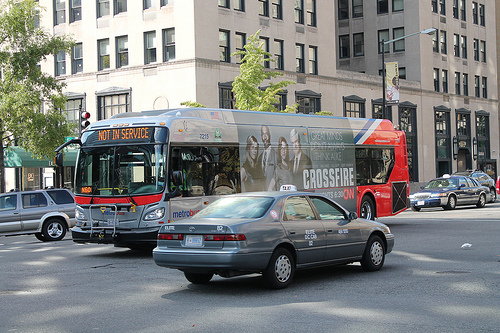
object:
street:
[0, 194, 500, 333]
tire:
[34, 218, 67, 243]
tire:
[261, 246, 297, 291]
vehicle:
[0, 188, 78, 244]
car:
[149, 184, 395, 291]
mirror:
[349, 212, 358, 221]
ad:
[230, 111, 360, 220]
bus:
[53, 106, 411, 250]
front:
[70, 116, 171, 244]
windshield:
[74, 126, 171, 198]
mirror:
[54, 153, 63, 167]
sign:
[80, 126, 155, 146]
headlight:
[74, 207, 89, 222]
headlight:
[142, 206, 167, 222]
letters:
[302, 169, 310, 189]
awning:
[2, 145, 93, 168]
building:
[0, 0, 500, 206]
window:
[52, 0, 67, 26]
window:
[54, 45, 67, 78]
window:
[70, 42, 83, 76]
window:
[97, 37, 111, 71]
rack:
[89, 204, 119, 242]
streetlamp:
[377, 27, 436, 121]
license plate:
[184, 234, 203, 247]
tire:
[360, 234, 387, 273]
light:
[80, 111, 91, 138]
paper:
[460, 242, 473, 249]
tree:
[0, 1, 79, 210]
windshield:
[191, 195, 276, 218]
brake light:
[157, 233, 185, 241]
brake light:
[204, 234, 247, 242]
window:
[306, 195, 348, 221]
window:
[281, 194, 319, 222]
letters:
[144, 127, 149, 138]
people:
[267, 136, 295, 192]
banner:
[384, 61, 400, 107]